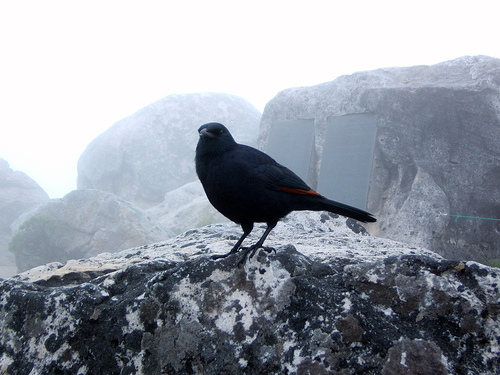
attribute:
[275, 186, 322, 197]
feather — red, like a line, orange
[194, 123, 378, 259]
bird — black, crow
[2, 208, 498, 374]
rock — gray, black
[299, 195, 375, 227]
tail feathers — long, black, pointed down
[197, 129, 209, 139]
beak — tiny, black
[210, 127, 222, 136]
eye — round, black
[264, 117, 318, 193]
plaque — gray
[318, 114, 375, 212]
plaque — gray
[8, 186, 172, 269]
boulder — large, gray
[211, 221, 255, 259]
leg — skinny, black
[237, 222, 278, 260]
leg — skinny, black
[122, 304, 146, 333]
white patch — snow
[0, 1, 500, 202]
sky — cloudy, white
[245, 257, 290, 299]
white patch — snow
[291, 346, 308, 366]
white patch — snow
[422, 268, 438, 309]
white patch — snow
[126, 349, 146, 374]
white patch — snow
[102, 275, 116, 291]
white patch — snow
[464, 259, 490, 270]
white patch — snow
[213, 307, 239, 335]
white patch — snow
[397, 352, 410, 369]
white patch — snow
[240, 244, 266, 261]
foot — black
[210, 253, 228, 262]
foot — black